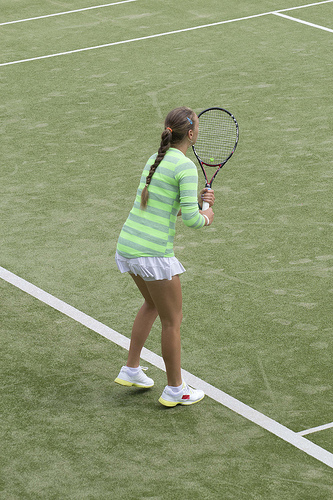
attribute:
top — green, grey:
[113, 146, 207, 263]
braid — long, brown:
[127, 130, 191, 205]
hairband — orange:
[162, 124, 174, 133]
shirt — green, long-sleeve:
[116, 146, 204, 258]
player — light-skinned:
[117, 90, 215, 405]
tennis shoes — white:
[111, 362, 206, 407]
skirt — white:
[110, 243, 193, 287]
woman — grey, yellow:
[110, 103, 218, 410]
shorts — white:
[135, 255, 177, 283]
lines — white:
[5, 8, 197, 66]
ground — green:
[12, 79, 90, 151]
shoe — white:
[155, 384, 208, 409]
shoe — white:
[111, 361, 156, 389]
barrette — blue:
[183, 107, 195, 127]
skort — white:
[92, 242, 205, 276]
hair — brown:
[137, 101, 189, 206]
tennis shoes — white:
[111, 355, 241, 410]